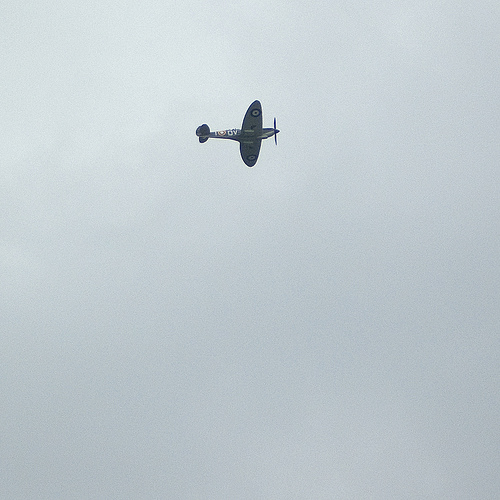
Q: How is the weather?
A: It is cloudy.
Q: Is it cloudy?
A: Yes, it is cloudy.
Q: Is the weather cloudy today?
A: Yes, it is cloudy.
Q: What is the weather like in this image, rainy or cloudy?
A: It is cloudy.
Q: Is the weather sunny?
A: No, it is cloudy.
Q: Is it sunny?
A: No, it is cloudy.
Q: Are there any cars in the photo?
A: No, there are no cars.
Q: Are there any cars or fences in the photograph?
A: No, there are no cars or fences.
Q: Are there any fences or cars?
A: No, there are no cars or fences.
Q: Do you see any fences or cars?
A: No, there are no cars or fences.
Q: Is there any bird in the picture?
A: No, there are no birds.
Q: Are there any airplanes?
A: Yes, there is an airplane.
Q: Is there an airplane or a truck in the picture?
A: Yes, there is an airplane.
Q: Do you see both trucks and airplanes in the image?
A: No, there is an airplane but no trucks.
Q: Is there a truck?
A: No, there are no trucks.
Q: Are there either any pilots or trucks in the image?
A: No, there are no trucks or pilots.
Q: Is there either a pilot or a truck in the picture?
A: No, there are no trucks or pilots.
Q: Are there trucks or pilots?
A: No, there are no trucks or pilots.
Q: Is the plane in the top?
A: Yes, the plane is in the top of the image.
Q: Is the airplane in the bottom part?
A: No, the airplane is in the top of the image.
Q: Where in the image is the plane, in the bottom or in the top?
A: The plane is in the top of the image.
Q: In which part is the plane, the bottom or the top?
A: The plane is in the top of the image.